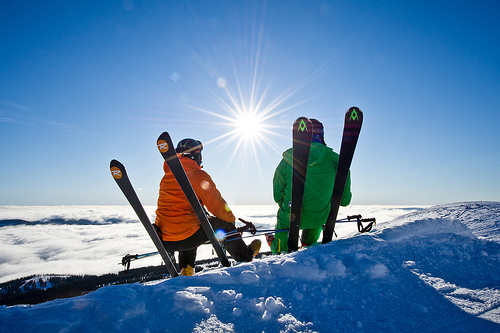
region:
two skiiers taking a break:
[93, 99, 393, 283]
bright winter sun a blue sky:
[157, 25, 327, 183]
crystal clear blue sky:
[4, 1, 492, 206]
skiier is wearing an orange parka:
[138, 119, 266, 277]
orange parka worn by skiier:
[155, 149, 238, 250]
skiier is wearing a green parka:
[270, 101, 350, 246]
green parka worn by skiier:
[265, 137, 355, 226]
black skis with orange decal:
[105, 126, 234, 276]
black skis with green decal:
[282, 101, 371, 256]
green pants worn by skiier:
[272, 220, 340, 262]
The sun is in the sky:
[165, 49, 330, 171]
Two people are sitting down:
[128, 109, 360, 283]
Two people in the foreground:
[135, 113, 359, 276]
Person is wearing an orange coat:
[145, 145, 241, 251]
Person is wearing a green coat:
[257, 132, 357, 252]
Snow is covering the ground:
[3, 194, 498, 329]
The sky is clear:
[6, 2, 499, 212]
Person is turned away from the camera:
[136, 109, 353, 274]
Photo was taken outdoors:
[3, 6, 498, 331]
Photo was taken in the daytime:
[100, 103, 365, 288]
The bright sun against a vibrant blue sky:
[181, 44, 300, 179]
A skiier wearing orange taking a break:
[104, 123, 262, 272]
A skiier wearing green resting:
[270, 110, 382, 247]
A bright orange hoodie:
[153, 157, 240, 242]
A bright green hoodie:
[280, 139, 360, 221]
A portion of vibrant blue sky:
[5, 5, 176, 105]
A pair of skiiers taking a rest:
[98, 104, 390, 271]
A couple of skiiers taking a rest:
[101, 96, 389, 288]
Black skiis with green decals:
[288, 103, 365, 247]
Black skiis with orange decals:
[100, 124, 225, 279]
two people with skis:
[106, 105, 376, 274]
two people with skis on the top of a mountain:
[107, 105, 377, 268]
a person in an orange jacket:
[110, 134, 262, 267]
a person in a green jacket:
[272, 108, 366, 256]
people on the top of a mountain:
[109, 107, 360, 268]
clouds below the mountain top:
[4, 199, 426, 275]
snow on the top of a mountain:
[5, 224, 477, 331]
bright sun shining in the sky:
[171, 64, 315, 175]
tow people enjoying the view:
[108, 103, 377, 265]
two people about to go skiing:
[104, 109, 379, 268]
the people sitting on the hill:
[100, 94, 376, 284]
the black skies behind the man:
[286, 105, 360, 250]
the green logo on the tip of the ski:
[297, 115, 312, 137]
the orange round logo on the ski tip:
[109, 163, 122, 180]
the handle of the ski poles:
[347, 211, 379, 233]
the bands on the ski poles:
[356, 218, 373, 234]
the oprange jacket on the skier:
[160, 152, 233, 244]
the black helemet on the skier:
[177, 133, 202, 165]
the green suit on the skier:
[269, 143, 354, 255]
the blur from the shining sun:
[200, 66, 289, 166]